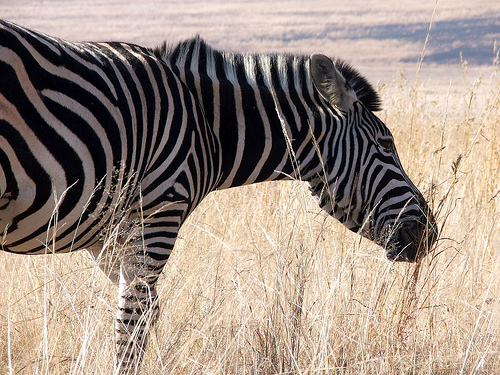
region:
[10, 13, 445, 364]
A zebra eating tall grass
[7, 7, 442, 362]
A zebra eating tall grass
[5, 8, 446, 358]
A zebra eating tall grass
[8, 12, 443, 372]
A zebra eating tall grass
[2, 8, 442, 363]
A zebra eating tall grass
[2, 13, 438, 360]
A zebra eating tall grass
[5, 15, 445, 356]
A zebra eating tall grass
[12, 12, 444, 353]
A zebra eating tall grass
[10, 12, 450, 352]
A zebra eating tall grass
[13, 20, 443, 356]
A zebra eating tall grass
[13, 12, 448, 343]
A zebra eating tall grass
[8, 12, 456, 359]
A zebra eating tall grass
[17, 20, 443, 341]
A zebra eating tall grass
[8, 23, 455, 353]
A zebra eating tall grass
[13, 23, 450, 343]
A zebra eating tall grass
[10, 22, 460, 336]
A zebra eating tall grass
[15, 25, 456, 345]
A zebra eating tall grass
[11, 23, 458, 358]
A zebra eating tall grass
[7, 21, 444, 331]
A zebra eating tall grass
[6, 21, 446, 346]
A zebra eating tall grass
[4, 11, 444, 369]
The zebra eats grass.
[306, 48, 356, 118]
The zebra's ear.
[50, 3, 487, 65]
The brush land.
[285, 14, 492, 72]
Shadow's on the land.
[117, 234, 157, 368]
The zebra's leg.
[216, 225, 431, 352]
The dry grass is still food.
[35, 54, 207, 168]
Perfect black and white stripes.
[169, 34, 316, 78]
The zebra's mane.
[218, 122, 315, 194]
The zebra's neck.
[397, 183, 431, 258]
zebra has black nose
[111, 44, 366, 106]
black and white mane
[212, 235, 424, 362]
long brown grass near zebra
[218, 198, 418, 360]
brown grass is wiry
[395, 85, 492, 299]
long stalks on grass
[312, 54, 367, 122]
zebra has white ears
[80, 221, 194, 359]
small stripes on legs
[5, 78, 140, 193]
large stripes on flank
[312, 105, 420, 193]
thin stripes on face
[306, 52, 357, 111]
A zebras right ear.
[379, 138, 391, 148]
Zebras eye that is black.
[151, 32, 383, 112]
Black and white zebra mane.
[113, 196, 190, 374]
A zebras right leg.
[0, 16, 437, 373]
Black and white zebra.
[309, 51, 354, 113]
Right ear of a zebra.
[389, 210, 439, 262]
A black snout of a zebra.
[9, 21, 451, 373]
A zebra in the grass.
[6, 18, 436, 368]
The zebra is black and white.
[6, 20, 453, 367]
The zebra has a striped pattern on it's fur.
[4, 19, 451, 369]
The zebra is in the tall brown grass.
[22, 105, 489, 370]
The tall grass surrounds the animal.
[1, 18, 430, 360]
A zebra.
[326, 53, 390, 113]
A short spiky mane of black hair.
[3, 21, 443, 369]
The zebra is not eating the grass.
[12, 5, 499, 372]
The zebra stands in a field.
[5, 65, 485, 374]
Tall brown grass around the zebra.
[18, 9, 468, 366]
the zebra is black and white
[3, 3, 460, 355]
the zebra has stripes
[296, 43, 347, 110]
ear of the zebra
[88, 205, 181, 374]
legs of the zebra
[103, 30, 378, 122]
mane on the zebra